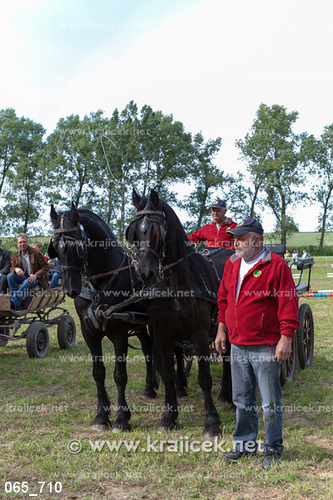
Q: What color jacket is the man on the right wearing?
A: Red.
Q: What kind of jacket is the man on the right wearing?
A: Fleece.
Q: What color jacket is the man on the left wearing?
A: Brown.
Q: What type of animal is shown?
A: Horses.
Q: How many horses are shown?
A: 2.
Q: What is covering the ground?
A: Grass.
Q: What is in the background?
A: Trees.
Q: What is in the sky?
A: Clouds.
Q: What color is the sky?
A: Blue.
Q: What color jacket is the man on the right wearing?
A: Red.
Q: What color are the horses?
A: Black.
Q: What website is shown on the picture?
A: Www.krajicek.net.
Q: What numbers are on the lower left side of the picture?
A: 065_710.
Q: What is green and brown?
A: Grass.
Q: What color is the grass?
A: Green and brown.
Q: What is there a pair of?
A: Black horses.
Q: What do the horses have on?
A: Blinders.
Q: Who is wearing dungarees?
A: A man.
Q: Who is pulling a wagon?
A: The horses.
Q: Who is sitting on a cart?
A: A man.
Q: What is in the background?
A: Green trees.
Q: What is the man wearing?
A: Red fleece jacket.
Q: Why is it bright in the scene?
A: It is daytime.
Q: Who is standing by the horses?
A: A man.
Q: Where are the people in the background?
A: In a wagon.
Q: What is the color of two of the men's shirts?
A: Red.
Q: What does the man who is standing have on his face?
A: Hair.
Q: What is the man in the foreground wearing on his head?
A: A hat.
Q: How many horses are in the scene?
A: Two.